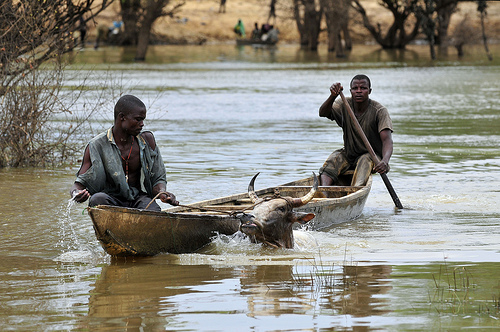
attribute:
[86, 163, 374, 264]
kayak — old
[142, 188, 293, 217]
leash — brown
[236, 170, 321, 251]
cow — horned, two horned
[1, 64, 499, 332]
water — smooth, flood, murky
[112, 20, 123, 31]
shirt — bright blue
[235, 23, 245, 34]
shirt — bright green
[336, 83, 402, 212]
paddle — brown, wooden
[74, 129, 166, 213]
clothes — torn, blue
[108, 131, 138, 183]
necklace — red